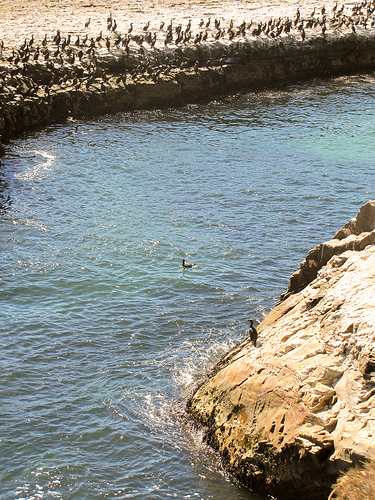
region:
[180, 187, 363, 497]
rocks next to the water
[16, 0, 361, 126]
a long rock ledge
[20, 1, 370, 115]
multiple birds on rock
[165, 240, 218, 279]
bird in the water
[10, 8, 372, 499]
a bright and sunny day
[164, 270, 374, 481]
rocks are light brown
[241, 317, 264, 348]
a duck on a cliff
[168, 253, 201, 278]
a duck in the water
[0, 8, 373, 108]
ducks gathered around a cliff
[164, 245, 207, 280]
a bird hunting for fishing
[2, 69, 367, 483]
a stream of water running through a rocky valley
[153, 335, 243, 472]
water crashing on a rock shore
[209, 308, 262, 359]
a bird looking for fish to eat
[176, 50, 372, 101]
a small enclosure under a jagged cliff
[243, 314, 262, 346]
animal standing on a rocky ledge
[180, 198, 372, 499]
tall ledge made of brown rock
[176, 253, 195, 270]
small duck floating in the water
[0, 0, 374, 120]
gigantic flock of birds standing on a ledge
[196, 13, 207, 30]
bird standing on some bare dirt ground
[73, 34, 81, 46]
bird standing on some bare dirt ground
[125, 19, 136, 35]
bird standing on some bare dirt ground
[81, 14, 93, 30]
bird standing on some bare dirt ground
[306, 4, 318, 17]
bird standing on some bare dirt ground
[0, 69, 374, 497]
river is full of dark blue water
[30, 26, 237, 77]
this is a group of animals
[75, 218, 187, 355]
the water is choppy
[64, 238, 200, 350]
the water is running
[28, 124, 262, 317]
this is a canyon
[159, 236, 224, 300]
the duck is floating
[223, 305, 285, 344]
the duck is on the ledge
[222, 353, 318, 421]
the ledge is rocky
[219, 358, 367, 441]
the ledge is light brown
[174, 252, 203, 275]
bird on the water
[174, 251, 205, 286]
bird on the water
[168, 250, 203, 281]
bird on the water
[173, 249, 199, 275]
bird on the water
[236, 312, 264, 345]
the bird is black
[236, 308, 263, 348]
the bird is black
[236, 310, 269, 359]
the bird is black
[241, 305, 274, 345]
the bird is black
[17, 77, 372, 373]
this is a river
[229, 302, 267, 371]
this is a bird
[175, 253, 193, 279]
this is a bird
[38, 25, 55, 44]
a bird on the beach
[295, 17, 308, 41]
a bird on the beach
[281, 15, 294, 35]
a bird on the beach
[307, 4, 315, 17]
a bird on the beach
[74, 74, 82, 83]
a bird on the beach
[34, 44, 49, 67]
a bird on the beach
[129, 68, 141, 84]
a bird on the beach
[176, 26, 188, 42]
a bird on the beach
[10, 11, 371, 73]
several birds on a beach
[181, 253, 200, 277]
a bird in the water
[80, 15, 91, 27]
a bird on the beach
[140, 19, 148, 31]
a bird on the beach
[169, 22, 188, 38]
a bird on the beach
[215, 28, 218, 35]
a bird on the beach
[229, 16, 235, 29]
a bird on the beach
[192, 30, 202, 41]
a bird on the beach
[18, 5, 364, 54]
the birds along the edge